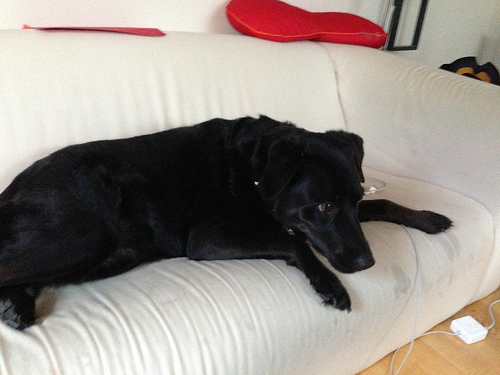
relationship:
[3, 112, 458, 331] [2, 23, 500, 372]
dog on couch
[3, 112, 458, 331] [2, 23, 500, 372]
dog laying on couch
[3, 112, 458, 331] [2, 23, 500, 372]
dog lying on couch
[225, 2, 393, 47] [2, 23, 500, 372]
pillow on top of couch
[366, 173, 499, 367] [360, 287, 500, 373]
wire on floor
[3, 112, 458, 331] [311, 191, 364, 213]
dog with eyes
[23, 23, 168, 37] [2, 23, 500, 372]
item on couch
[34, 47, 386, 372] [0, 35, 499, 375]
row in fabric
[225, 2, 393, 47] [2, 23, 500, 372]
pillow on couch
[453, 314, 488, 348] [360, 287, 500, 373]
box on floor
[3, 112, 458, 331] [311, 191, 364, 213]
dog has eyes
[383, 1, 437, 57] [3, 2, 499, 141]
mirror in background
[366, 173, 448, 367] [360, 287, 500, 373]
wire on floor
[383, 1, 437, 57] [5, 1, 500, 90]
mirror on wall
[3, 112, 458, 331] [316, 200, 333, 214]
dog has eye